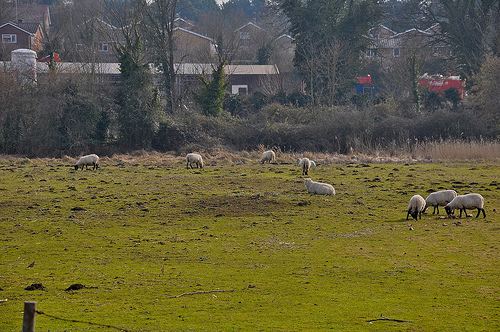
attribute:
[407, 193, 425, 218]
sheep — eating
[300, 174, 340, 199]
sheep — resting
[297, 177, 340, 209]
sheep — laying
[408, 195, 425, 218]
sheep — grazing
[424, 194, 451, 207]
sheep — grazing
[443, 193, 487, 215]
sheep — grazing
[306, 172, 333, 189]
sheep — grazing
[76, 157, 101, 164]
sheep — grazing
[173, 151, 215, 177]
animal — one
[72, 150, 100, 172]
sheep — eating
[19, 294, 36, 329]
post — wooden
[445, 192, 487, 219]
sheep — eating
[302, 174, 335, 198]
sheep — resting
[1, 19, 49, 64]
house — distant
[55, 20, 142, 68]
house — distant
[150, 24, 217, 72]
house — distant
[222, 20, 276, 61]
house — distant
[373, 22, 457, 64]
house — distant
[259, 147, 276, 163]
sheep — grazing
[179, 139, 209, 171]
sheep — eating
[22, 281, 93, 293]
rocks — black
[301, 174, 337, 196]
animal — laying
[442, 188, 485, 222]
sheep — grazing